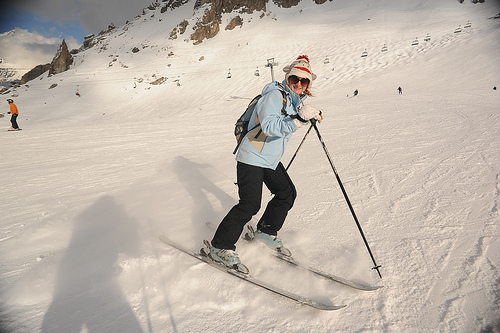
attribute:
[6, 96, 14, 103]
cap — orange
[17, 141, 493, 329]
snow — white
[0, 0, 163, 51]
sky — blue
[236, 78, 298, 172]
jacket — blue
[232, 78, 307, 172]
jacket — blue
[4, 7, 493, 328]
mountain — rocky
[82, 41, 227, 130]
hillside — snow-less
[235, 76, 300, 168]
jacket — blue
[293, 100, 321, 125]
gloves — white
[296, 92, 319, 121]
gloves — white